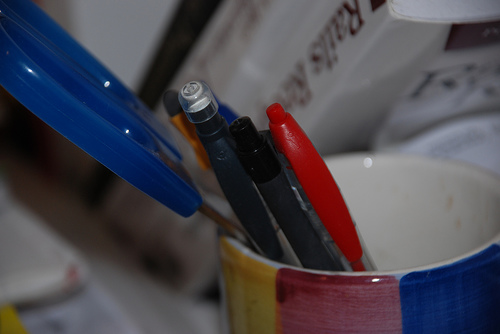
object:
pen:
[265, 101, 376, 272]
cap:
[177, 80, 219, 124]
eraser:
[181, 81, 203, 103]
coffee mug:
[216, 150, 500, 334]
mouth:
[223, 156, 499, 273]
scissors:
[1, 0, 263, 257]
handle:
[1, 1, 203, 218]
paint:
[275, 267, 402, 334]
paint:
[399, 243, 500, 333]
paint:
[217, 232, 278, 334]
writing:
[272, 1, 386, 112]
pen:
[226, 115, 351, 273]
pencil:
[178, 80, 297, 267]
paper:
[1, 302, 27, 334]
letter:
[342, 1, 365, 36]